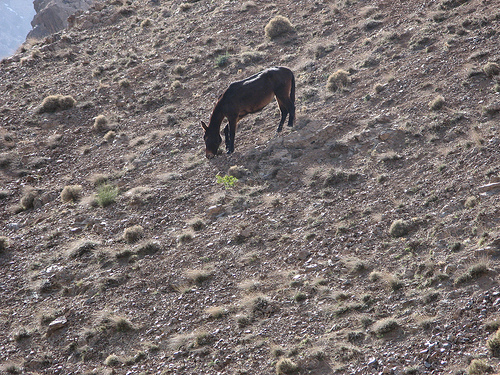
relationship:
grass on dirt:
[238, 292, 261, 316] [3, 0, 495, 369]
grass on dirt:
[368, 315, 401, 335] [3, 0, 495, 369]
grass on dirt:
[275, 357, 301, 372] [3, 0, 495, 369]